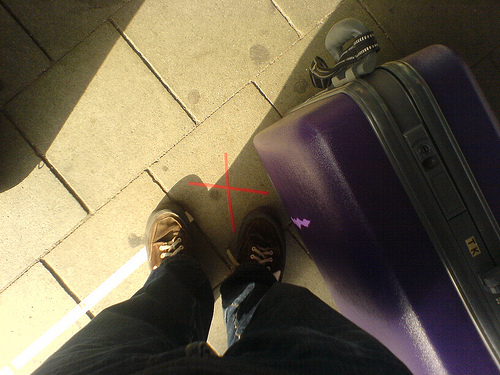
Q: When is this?
A: Daytime.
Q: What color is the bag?
A: Blue.